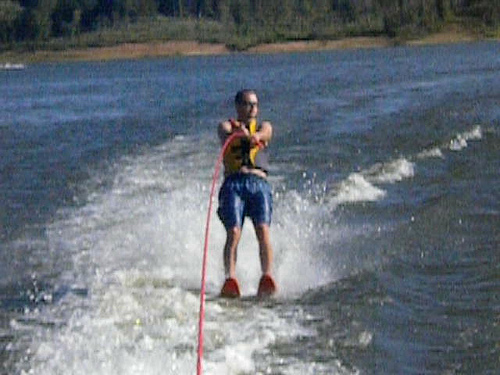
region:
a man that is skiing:
[116, 43, 368, 351]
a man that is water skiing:
[125, 45, 413, 325]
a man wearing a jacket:
[165, 71, 383, 325]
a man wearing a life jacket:
[192, 76, 307, 275]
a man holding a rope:
[164, 71, 375, 360]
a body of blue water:
[104, 54, 401, 364]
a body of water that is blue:
[27, 53, 462, 371]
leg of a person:
[215, 211, 247, 278]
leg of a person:
[243, 227, 297, 279]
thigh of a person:
[215, 185, 247, 226]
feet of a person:
[219, 278, 236, 298]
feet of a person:
[257, 281, 284, 302]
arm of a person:
[220, 125, 245, 146]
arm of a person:
[249, 113, 280, 152]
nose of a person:
[245, 99, 260, 109]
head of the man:
[218, 76, 284, 126]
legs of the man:
[186, 210, 296, 283]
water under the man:
[49, 198, 196, 338]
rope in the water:
[149, 215, 239, 308]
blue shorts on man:
[193, 164, 292, 254]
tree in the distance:
[41, 10, 253, 57]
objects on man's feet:
[201, 242, 296, 312]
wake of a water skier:
[41, 94, 498, 246]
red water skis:
[217, 274, 274, 299]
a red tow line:
[195, 116, 265, 374]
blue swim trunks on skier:
[217, 176, 274, 228]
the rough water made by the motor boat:
[23, 213, 305, 370]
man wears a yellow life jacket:
[217, 118, 265, 168]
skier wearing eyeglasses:
[235, 98, 262, 111]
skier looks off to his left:
[214, 90, 276, 149]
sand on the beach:
[19, 37, 499, 50]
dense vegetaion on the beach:
[3, 1, 495, 42]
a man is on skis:
[211, 86, 276, 301]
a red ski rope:
[193, 122, 262, 372]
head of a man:
[234, 87, 260, 120]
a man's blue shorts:
[213, 171, 275, 233]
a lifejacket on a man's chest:
[223, 122, 270, 174]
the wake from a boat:
[35, 136, 351, 374]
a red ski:
[222, 278, 238, 302]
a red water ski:
[258, 272, 281, 299]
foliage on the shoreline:
[0, 0, 499, 51]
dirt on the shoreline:
[0, 33, 499, 60]